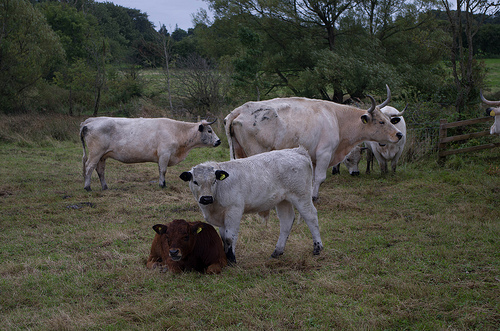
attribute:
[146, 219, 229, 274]
cow — brown, resting, small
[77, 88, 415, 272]
cows — hoofed, colored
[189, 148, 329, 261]
cow — white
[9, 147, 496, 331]
grass — short, green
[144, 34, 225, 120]
tree — dead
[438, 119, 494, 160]
fence — wooden, slatted